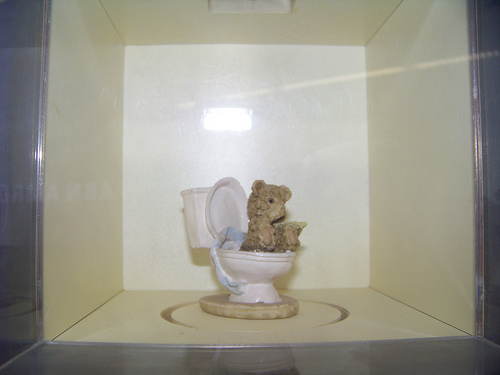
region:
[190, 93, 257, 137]
light reflecting on the wall.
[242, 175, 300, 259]
the bear is brown.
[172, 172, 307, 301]
bear on the toilet.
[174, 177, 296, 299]
the toilet is white.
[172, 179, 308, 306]
the bear and toilet are miniature.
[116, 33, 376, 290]
the wall is white.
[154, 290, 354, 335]
brown circle on the ground.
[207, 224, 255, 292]
blue ribbon on toilet.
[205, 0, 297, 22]
white vent on the ceiling.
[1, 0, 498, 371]
the frame is grey.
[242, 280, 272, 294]
edge of a cup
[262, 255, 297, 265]
edge of a cup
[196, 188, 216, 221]
edge of a lid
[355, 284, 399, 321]
part of a floor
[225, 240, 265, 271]
edge of a toilet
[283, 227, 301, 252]
leg of a doll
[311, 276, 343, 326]
part of a floor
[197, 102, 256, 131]
Reflection of light on plastic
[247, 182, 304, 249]
Stuffed bear sitting on a toilet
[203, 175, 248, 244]
Toilet lid pushed up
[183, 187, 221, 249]
Front of a toilet tank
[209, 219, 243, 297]
Blue blanket on a toilet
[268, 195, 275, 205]
Black eye of a stuffed bear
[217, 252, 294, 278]
Bowl of a toilet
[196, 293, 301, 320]
Round platform under a toilet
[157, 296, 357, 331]
Circle on a white ground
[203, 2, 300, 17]
Square in the ceiling of a box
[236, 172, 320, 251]
A small brown teddy bear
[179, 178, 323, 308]
a miniature toilet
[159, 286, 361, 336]
A circular groove at the base of the toilet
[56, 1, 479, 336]
Glass in front of display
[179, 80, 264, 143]
a reflection of light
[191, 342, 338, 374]
reflection of a person's lower body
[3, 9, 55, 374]
metal display case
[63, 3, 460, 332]
The white interior of the display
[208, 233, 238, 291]
some blue ceramic coming from the toilet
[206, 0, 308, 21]
A light in the display case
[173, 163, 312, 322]
teddy bear sits in toilet, teddy bear sits alone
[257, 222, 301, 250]
teddy bear has little beige leather pads on underfeet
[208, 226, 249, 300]
a blue blanket is somehow involved w/ toilet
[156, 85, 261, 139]
rectangular white light reflected on scene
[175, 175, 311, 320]
toilet is toy, & miniature too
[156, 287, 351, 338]
enigmatic broken circle surrounds toy toilet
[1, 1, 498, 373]
scene is somehow framed or on monitor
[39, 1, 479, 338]
diorama's walls are light mustard yellow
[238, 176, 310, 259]
teddy bear is vaguely expressionless even while falling into toilet bowl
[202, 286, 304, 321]
toy toilet rests on a small round pancake-like stand